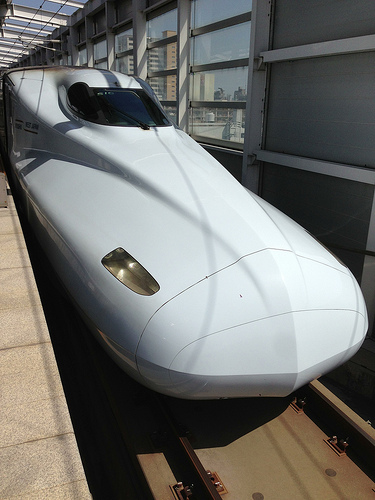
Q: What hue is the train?
A: White.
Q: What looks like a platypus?
A: The train.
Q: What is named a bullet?
A: The train.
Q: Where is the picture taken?
A: Train station.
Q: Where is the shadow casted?
A: The train.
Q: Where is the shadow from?
A: Train.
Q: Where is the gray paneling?
A: On wall.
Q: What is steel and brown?
A: Train track.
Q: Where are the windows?
A: Side of vehicle.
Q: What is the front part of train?
A: Nose.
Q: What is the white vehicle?
A: Train.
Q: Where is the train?
A: On tracks.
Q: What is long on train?
A: Nose.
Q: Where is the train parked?
A: Train station.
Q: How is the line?
A: Thin.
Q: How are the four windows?
A: In row.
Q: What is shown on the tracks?
A: A futuristic train car.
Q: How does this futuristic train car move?
A: On tracks.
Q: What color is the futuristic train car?
A: White.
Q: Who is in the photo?
A: No one.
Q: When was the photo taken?
A: Daytime.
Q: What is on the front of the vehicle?
A: Lights.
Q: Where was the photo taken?
A: In a train station.